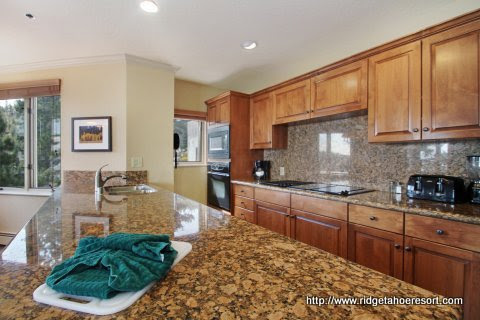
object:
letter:
[305, 292, 311, 305]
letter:
[317, 295, 325, 307]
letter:
[331, 295, 343, 307]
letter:
[339, 294, 350, 305]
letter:
[348, 290, 357, 304]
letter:
[453, 296, 462, 304]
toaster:
[406, 172, 466, 206]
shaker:
[386, 179, 399, 199]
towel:
[45, 228, 182, 302]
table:
[3, 187, 465, 317]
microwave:
[198, 119, 234, 168]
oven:
[202, 164, 234, 213]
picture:
[66, 109, 114, 150]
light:
[140, 4, 160, 15]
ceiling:
[3, 1, 477, 98]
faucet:
[85, 157, 144, 198]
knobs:
[412, 123, 428, 138]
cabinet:
[417, 7, 478, 139]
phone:
[167, 128, 187, 169]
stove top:
[291, 175, 372, 203]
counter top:
[229, 171, 477, 225]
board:
[28, 226, 200, 318]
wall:
[1, 54, 179, 192]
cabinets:
[418, 22, 476, 148]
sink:
[294, 177, 391, 206]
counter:
[239, 170, 477, 215]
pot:
[252, 164, 267, 180]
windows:
[2, 88, 61, 196]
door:
[245, 93, 275, 154]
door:
[307, 54, 369, 119]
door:
[363, 38, 422, 140]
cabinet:
[363, 34, 425, 150]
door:
[425, 18, 478, 142]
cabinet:
[253, 203, 294, 239]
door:
[292, 206, 348, 260]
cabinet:
[284, 208, 349, 258]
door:
[344, 222, 404, 279]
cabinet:
[342, 221, 405, 280]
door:
[284, 208, 350, 266]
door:
[250, 200, 295, 245]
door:
[273, 81, 318, 128]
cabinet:
[263, 73, 317, 129]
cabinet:
[243, 90, 290, 153]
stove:
[197, 117, 233, 208]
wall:
[171, 163, 206, 211]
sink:
[91, 164, 156, 202]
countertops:
[1, 183, 456, 319]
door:
[367, 44, 425, 143]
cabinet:
[305, 56, 368, 122]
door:
[198, 90, 233, 127]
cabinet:
[202, 88, 256, 182]